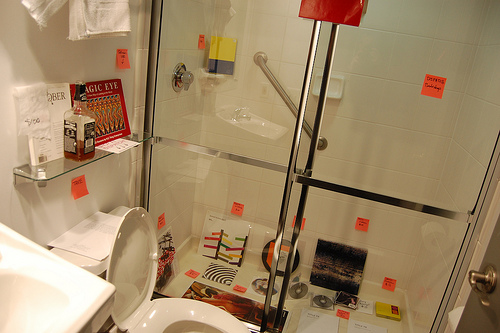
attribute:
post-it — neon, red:
[420, 74, 445, 96]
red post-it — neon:
[421, 72, 444, 99]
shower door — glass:
[261, 2, 496, 329]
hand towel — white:
[21, 6, 56, 28]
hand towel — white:
[75, 21, 137, 42]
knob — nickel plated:
[462, 260, 499, 304]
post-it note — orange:
[420, 71, 448, 101]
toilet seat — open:
[104, 204, 251, 331]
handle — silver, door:
[466, 265, 496, 306]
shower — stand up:
[141, 0, 495, 328]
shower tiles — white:
[372, 121, 450, 177]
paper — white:
[295, 295, 332, 331]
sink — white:
[1, 223, 113, 329]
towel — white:
[38, 10, 145, 56]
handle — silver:
[253, 52, 325, 150]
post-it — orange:
[423, 70, 445, 99]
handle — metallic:
[464, 264, 497, 294]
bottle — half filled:
[62, 81, 96, 161]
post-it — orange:
[134, 199, 191, 246]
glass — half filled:
[61, 84, 93, 166]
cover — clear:
[254, 229, 309, 279]